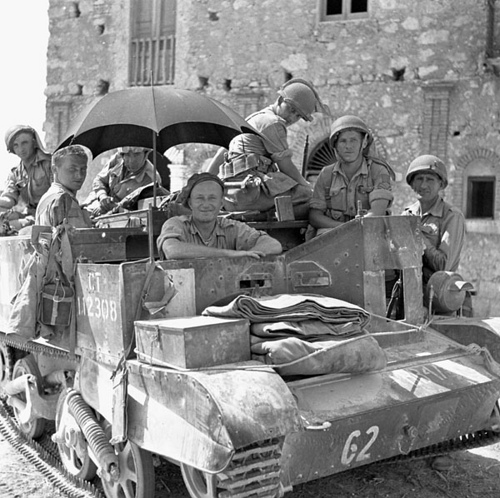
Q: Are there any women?
A: No, there are no women.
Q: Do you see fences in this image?
A: No, there are no fences.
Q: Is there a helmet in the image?
A: Yes, there is a helmet.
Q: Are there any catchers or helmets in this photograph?
A: Yes, there is a helmet.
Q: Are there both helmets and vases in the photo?
A: No, there is a helmet but no vases.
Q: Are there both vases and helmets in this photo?
A: No, there is a helmet but no vases.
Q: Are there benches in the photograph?
A: No, there are no benches.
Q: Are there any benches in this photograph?
A: No, there are no benches.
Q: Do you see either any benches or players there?
A: No, there are no benches or players.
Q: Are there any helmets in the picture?
A: Yes, there is a helmet.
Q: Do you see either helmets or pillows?
A: Yes, there is a helmet.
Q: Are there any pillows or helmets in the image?
A: Yes, there is a helmet.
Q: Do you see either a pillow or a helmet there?
A: Yes, there is a helmet.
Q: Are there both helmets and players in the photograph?
A: No, there is a helmet but no players.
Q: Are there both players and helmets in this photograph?
A: No, there is a helmet but no players.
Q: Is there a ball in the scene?
A: No, there are no balls.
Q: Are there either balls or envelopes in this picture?
A: No, there are no balls or envelopes.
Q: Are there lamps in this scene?
A: No, there are no lamps.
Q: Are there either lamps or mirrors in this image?
A: No, there are no lamps or mirrors.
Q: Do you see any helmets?
A: Yes, there is a helmet.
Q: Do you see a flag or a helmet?
A: Yes, there is a helmet.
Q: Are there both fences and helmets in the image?
A: No, there is a helmet but no fences.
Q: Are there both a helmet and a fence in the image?
A: No, there is a helmet but no fences.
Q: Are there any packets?
A: No, there are no packets.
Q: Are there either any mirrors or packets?
A: No, there are no packets or mirrors.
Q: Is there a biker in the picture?
A: No, there are no bikers.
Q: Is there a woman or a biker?
A: No, there are no bikers or women.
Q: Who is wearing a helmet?
A: The soldier is wearing a helmet.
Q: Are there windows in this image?
A: Yes, there is a window.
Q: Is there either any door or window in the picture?
A: Yes, there is a window.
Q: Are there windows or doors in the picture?
A: Yes, there is a window.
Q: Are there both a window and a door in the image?
A: No, there is a window but no doors.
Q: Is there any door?
A: No, there are no doors.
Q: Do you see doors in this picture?
A: No, there are no doors.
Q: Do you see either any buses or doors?
A: No, there are no doors or buses.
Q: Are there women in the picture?
A: No, there are no women.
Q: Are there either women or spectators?
A: No, there are no women or spectators.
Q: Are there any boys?
A: No, there are no boys.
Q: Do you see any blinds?
A: No, there are no blinds.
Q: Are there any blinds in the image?
A: No, there are no blinds.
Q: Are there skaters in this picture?
A: No, there are no skaters.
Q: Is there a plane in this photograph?
A: No, there are no airplanes.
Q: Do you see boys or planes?
A: No, there are no planes or boys.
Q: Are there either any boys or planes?
A: No, there are no planes or boys.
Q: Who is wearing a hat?
A: The soldier is wearing a hat.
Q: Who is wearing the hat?
A: The soldier is wearing a hat.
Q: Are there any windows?
A: Yes, there is a window.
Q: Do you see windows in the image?
A: Yes, there is a window.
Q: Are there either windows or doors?
A: Yes, there is a window.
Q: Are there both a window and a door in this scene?
A: No, there is a window but no doors.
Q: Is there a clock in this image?
A: No, there are no clocks.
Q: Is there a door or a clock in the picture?
A: No, there are no clocks or doors.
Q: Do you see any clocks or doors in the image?
A: No, there are no clocks or doors.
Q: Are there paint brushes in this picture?
A: No, there are no paint brushes.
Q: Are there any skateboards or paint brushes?
A: No, there are no paint brushes or skateboards.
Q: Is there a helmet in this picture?
A: Yes, there is a helmet.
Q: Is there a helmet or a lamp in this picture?
A: Yes, there is a helmet.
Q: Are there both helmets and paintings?
A: No, there is a helmet but no paintings.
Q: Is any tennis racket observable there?
A: No, there are no rackets.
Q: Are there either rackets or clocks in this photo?
A: No, there are no rackets or clocks.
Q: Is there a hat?
A: Yes, there is a hat.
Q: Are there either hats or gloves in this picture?
A: Yes, there is a hat.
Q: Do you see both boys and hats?
A: No, there is a hat but no boys.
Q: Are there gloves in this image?
A: No, there are no gloves.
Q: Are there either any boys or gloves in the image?
A: No, there are no gloves or boys.